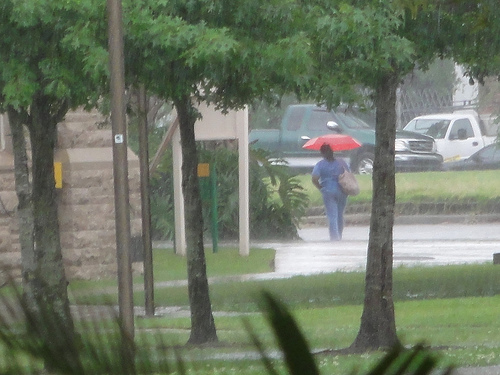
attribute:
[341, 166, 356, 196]
purse — brown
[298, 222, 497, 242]
asphalt — black 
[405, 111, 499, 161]
truck — white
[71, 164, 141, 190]
blocks — light beige, stone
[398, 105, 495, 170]
truck — white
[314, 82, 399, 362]
tree trunk — straight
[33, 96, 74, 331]
tree trunk — straight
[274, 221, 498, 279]
road — wet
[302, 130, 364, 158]
umbrella — red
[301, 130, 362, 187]
umbrella — open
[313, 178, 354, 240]
jeans — blue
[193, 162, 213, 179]
sign — yellow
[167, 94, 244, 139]
sign — white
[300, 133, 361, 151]
umbrella — red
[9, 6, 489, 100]
leaves — green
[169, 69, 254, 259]
wooden sign — white 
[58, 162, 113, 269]
wall — tan, stone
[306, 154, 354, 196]
shirt — blue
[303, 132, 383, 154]
umbrella — red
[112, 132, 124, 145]
sticker — white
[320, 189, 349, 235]
pants — blue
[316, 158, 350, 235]
outfit — blue